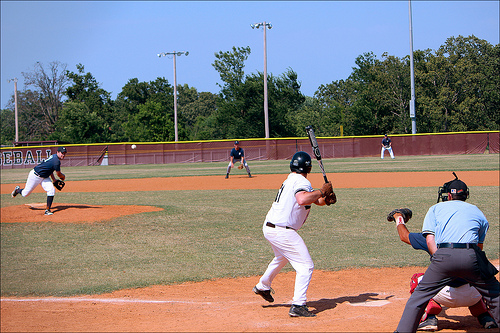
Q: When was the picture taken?
A: Daytime.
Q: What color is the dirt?
A: Brown.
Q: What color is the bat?
A: Black and white.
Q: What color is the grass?
A: Green.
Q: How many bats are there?
A: One.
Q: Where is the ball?
A: In the air.